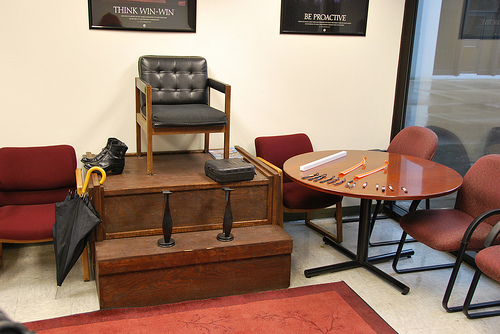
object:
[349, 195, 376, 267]
stem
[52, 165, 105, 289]
umbrella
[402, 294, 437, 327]
ground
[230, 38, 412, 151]
wall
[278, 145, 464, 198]
tabletop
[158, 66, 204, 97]
leather like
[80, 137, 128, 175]
boots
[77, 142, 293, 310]
shoeshine stand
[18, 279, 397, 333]
carpet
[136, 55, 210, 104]
backrest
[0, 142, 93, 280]
chair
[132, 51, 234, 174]
chair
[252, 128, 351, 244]
chair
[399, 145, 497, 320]
chair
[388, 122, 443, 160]
chair